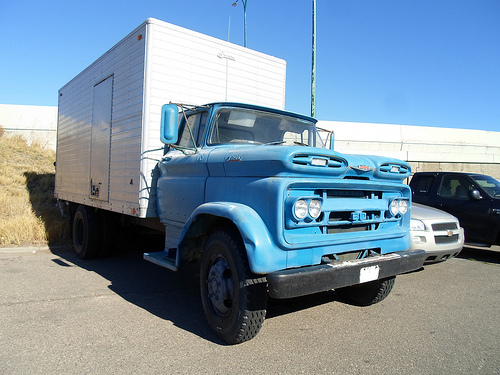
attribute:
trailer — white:
[52, 17, 287, 219]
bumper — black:
[274, 250, 426, 297]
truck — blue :
[228, 114, 396, 304]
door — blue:
[149, 102, 216, 225]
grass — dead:
[3, 137, 55, 239]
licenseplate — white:
[356, 262, 379, 285]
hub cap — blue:
[204, 260, 234, 317]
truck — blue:
[34, 18, 478, 348]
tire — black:
[69, 206, 101, 259]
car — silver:
[404, 192, 471, 264]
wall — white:
[1, 99, 496, 195]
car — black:
[378, 162, 491, 258]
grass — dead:
[1, 131, 67, 243]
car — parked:
[405, 195, 462, 270]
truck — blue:
[46, 12, 398, 363]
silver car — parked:
[409, 199, 464, 264]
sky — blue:
[2, 1, 499, 133]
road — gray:
[8, 242, 498, 373]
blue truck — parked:
[50, 17, 430, 348]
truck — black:
[408, 169, 498, 254]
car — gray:
[410, 200, 463, 265]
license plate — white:
[353, 264, 385, 287]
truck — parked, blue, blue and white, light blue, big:
[50, 18, 426, 345]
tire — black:
[195, 241, 276, 357]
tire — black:
[348, 255, 411, 305]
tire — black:
[48, 192, 100, 277]